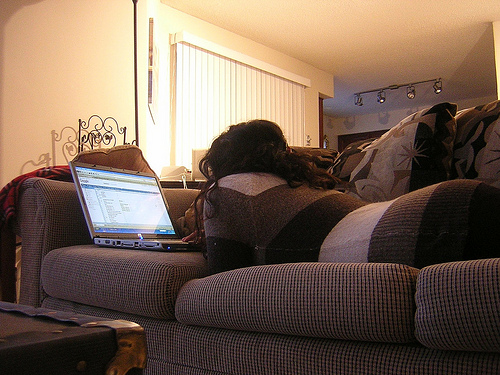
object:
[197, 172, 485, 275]
sweater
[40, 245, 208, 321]
cushion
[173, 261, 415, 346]
cushion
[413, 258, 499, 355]
cushion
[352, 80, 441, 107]
lighting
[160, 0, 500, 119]
ceiling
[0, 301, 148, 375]
table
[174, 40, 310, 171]
blinds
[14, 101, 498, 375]
couch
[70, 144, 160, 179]
pillow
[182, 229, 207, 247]
hand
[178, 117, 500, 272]
woman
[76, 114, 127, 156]
shelving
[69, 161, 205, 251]
laptop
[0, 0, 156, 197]
wall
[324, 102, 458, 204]
pillow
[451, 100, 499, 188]
pillow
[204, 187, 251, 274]
arm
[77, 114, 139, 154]
top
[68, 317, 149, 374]
corner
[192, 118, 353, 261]
hair